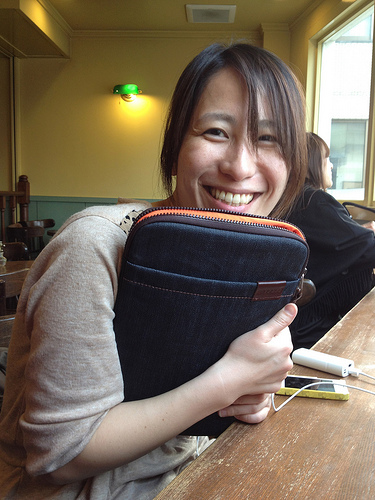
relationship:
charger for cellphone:
[291, 347, 356, 378] [276, 373, 349, 400]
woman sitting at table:
[0, 39, 308, 499] [148, 285, 374, 499]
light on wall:
[111, 84, 144, 102] [0, 30, 293, 201]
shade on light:
[113, 84, 139, 95] [111, 84, 144, 102]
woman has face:
[0, 39, 308, 499] [178, 67, 292, 216]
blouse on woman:
[0, 201, 208, 499] [0, 39, 308, 499]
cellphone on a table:
[276, 373, 349, 400] [148, 285, 374, 499]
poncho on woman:
[282, 186, 374, 328] [275, 131, 374, 356]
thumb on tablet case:
[263, 301, 299, 337] [113, 207, 309, 436]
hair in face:
[160, 38, 308, 220] [178, 67, 292, 216]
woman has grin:
[0, 39, 308, 499] [200, 182, 266, 213]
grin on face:
[200, 182, 266, 213] [178, 67, 292, 216]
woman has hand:
[0, 39, 308, 499] [231, 301, 298, 394]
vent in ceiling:
[187, 3, 237, 26] [0, 1, 319, 57]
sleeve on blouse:
[18, 214, 126, 476] [0, 201, 208, 499]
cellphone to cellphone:
[276, 373, 349, 400] [276, 373, 349, 400]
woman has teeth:
[0, 39, 308, 499] [208, 187, 254, 206]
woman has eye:
[0, 39, 308, 499] [202, 127, 227, 138]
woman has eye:
[0, 39, 308, 499] [256, 134, 276, 142]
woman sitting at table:
[275, 131, 374, 356] [148, 285, 374, 499]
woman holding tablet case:
[0, 39, 308, 499] [113, 207, 309, 436]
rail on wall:
[0, 173, 31, 244] [0, 30, 293, 201]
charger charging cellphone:
[291, 347, 356, 378] [276, 373, 349, 400]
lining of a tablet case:
[134, 209, 305, 239] [113, 207, 309, 436]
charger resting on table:
[291, 347, 356, 378] [148, 285, 374, 499]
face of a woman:
[178, 67, 292, 216] [0, 39, 308, 499]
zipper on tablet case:
[293, 275, 303, 302] [113, 207, 309, 436]